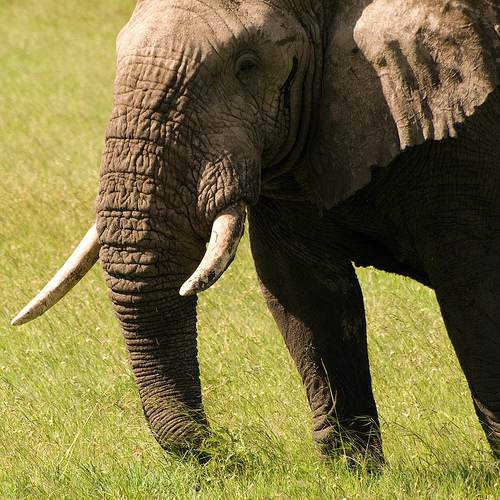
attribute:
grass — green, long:
[15, 462, 375, 500]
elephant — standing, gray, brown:
[8, 1, 496, 468]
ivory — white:
[13, 208, 255, 319]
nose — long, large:
[99, 158, 215, 454]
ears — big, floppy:
[321, 5, 497, 206]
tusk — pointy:
[184, 204, 248, 298]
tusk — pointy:
[17, 210, 99, 332]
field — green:
[12, 356, 435, 482]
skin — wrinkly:
[124, 124, 201, 248]